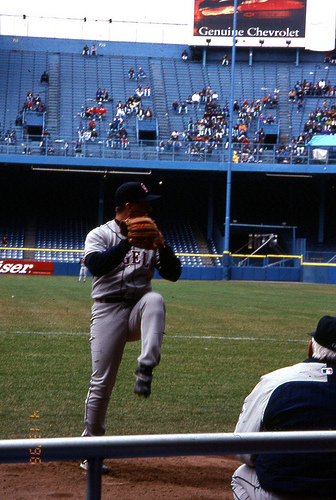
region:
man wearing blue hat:
[117, 188, 132, 198]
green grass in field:
[201, 355, 224, 379]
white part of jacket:
[258, 384, 267, 398]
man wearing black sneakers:
[130, 370, 158, 399]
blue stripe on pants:
[81, 387, 93, 411]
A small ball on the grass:
[7, 290, 18, 306]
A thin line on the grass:
[188, 327, 253, 346]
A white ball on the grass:
[3, 292, 26, 303]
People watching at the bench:
[185, 95, 227, 143]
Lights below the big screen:
[196, 31, 311, 50]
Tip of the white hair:
[309, 352, 331, 361]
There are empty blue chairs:
[39, 230, 81, 248]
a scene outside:
[6, 18, 331, 498]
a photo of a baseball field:
[2, 2, 335, 498]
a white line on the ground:
[3, 309, 335, 358]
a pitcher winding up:
[54, 165, 210, 497]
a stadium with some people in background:
[5, 20, 332, 191]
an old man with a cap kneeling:
[196, 305, 333, 493]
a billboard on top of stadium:
[182, 0, 320, 48]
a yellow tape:
[0, 231, 334, 284]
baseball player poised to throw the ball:
[81, 179, 183, 473]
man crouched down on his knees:
[227, 312, 335, 499]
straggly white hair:
[309, 334, 333, 359]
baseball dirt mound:
[0, 452, 245, 499]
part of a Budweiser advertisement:
[0, 257, 55, 276]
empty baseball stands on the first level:
[0, 225, 224, 282]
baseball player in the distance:
[75, 252, 87, 283]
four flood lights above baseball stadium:
[201, 37, 293, 47]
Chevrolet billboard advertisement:
[192, 0, 308, 40]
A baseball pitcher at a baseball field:
[72, 177, 184, 478]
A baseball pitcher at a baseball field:
[73, 173, 184, 473]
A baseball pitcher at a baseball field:
[73, 177, 189, 479]